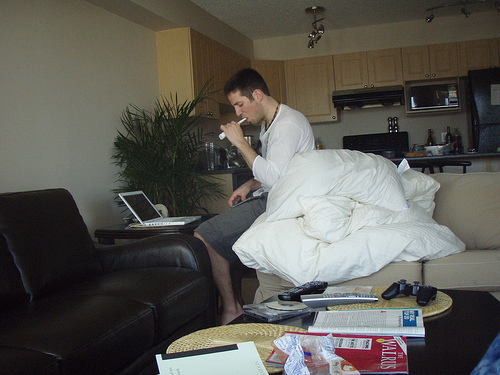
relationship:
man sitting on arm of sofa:
[195, 68, 318, 329] [255, 169, 499, 298]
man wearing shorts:
[195, 68, 318, 329] [196, 197, 266, 264]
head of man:
[225, 69, 276, 127] [195, 68, 318, 329]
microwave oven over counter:
[408, 82, 461, 110] [374, 150, 499, 160]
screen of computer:
[125, 191, 158, 220] [118, 187, 203, 228]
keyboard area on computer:
[149, 216, 200, 225] [118, 187, 203, 228]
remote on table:
[382, 280, 437, 305] [148, 288, 500, 374]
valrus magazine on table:
[263, 331, 408, 375] [148, 288, 500, 374]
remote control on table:
[281, 281, 328, 304] [148, 288, 500, 374]